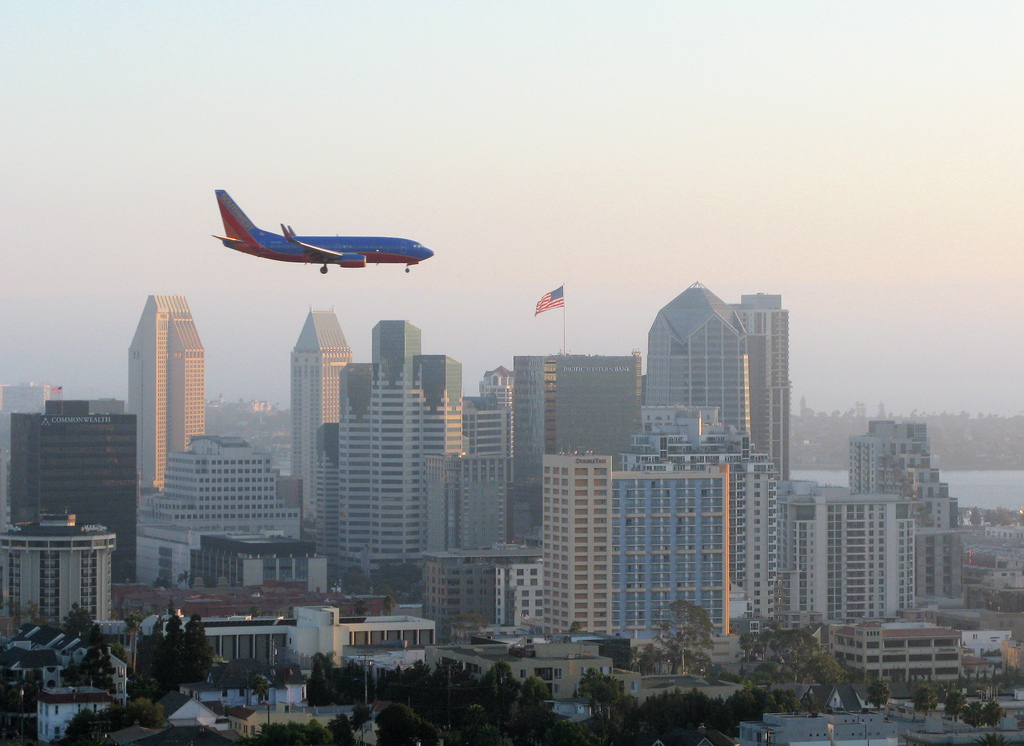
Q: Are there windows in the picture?
A: Yes, there are windows.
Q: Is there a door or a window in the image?
A: Yes, there are windows.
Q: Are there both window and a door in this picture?
A: No, there are windows but no doors.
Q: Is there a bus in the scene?
A: No, there are no buses.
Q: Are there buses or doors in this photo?
A: No, there are no buses or doors.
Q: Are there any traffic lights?
A: No, there are no traffic lights.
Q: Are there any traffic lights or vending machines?
A: No, there are no traffic lights or vending machines.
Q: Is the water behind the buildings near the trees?
A: Yes, the water is behind the buildings.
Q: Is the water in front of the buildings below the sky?
A: No, the water is behind the buildings.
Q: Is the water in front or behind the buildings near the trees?
A: The water is behind the buildings.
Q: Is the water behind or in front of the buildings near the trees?
A: The water is behind the buildings.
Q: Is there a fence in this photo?
A: No, there are no fences.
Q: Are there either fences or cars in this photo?
A: No, there are no fences or cars.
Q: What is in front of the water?
A: The buildings are in front of the water.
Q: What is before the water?
A: The buildings are in front of the water.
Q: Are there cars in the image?
A: No, there are no cars.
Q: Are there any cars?
A: No, there are no cars.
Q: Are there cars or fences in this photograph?
A: No, there are no cars or fences.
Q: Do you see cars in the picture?
A: No, there are no cars.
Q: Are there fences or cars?
A: No, there are no cars or fences.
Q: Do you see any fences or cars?
A: No, there are no cars or fences.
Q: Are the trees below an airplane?
A: Yes, the trees are below an airplane.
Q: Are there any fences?
A: No, there are no fences.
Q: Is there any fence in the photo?
A: No, there are no fences.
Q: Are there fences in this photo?
A: No, there are no fences.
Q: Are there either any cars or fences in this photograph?
A: No, there are no fences or cars.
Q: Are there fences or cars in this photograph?
A: No, there are no fences or cars.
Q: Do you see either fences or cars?
A: No, there are no fences or cars.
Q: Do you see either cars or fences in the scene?
A: No, there are no fences or cars.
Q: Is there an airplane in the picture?
A: Yes, there is an airplane.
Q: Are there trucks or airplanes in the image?
A: Yes, there is an airplane.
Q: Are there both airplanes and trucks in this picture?
A: No, there is an airplane but no trucks.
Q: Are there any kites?
A: No, there are no kites.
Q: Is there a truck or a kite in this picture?
A: No, there are no kites or trucks.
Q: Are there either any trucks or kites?
A: No, there are no kites or trucks.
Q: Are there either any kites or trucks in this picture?
A: No, there are no kites or trucks.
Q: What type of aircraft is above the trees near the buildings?
A: The aircraft is an airplane.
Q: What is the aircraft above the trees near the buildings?
A: The aircraft is an airplane.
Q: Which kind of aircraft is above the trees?
A: The aircraft is an airplane.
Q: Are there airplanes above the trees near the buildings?
A: Yes, there is an airplane above the trees.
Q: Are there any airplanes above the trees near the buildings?
A: Yes, there is an airplane above the trees.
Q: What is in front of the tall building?
A: The airplane is in front of the building.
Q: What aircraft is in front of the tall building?
A: The aircraft is an airplane.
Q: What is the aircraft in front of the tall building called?
A: The aircraft is an airplane.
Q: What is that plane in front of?
A: The plane is in front of the building.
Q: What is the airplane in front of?
A: The plane is in front of the building.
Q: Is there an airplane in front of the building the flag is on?
A: Yes, there is an airplane in front of the building.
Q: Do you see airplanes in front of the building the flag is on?
A: Yes, there is an airplane in front of the building.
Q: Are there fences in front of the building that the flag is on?
A: No, there is an airplane in front of the building.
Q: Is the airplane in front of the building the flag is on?
A: Yes, the airplane is in front of the building.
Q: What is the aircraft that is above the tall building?
A: The aircraft is an airplane.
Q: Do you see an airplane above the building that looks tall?
A: Yes, there is an airplane above the building.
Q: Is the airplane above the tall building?
A: Yes, the airplane is above the building.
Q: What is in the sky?
A: The airplane is in the sky.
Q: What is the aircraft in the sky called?
A: The aircraft is an airplane.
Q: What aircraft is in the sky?
A: The aircraft is an airplane.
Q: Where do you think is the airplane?
A: The airplane is in the sky.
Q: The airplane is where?
A: The airplane is in the sky.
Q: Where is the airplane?
A: The airplane is in the sky.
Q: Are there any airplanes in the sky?
A: Yes, there is an airplane in the sky.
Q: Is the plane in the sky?
A: Yes, the plane is in the sky.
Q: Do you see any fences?
A: No, there are no fences.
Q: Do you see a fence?
A: No, there are no fences.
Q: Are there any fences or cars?
A: No, there are no fences or cars.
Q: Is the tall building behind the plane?
A: Yes, the building is behind the plane.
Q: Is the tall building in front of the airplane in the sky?
A: No, the building is behind the airplane.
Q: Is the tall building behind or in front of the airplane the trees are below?
A: The building is behind the plane.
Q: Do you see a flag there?
A: Yes, there is a flag.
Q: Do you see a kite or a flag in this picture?
A: Yes, there is a flag.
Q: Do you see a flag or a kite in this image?
A: Yes, there is a flag.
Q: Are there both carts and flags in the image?
A: No, there is a flag but no carts.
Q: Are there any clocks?
A: No, there are no clocks.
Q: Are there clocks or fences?
A: No, there are no clocks or fences.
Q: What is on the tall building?
A: The flag is on the building.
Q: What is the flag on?
A: The flag is on the building.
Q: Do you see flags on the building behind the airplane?
A: Yes, there is a flag on the building.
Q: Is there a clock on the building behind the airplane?
A: No, there is a flag on the building.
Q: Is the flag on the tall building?
A: Yes, the flag is on the building.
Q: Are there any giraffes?
A: No, there are no giraffes.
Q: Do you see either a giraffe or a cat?
A: No, there are no giraffes or cats.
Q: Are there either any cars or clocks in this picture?
A: No, there are no cars or clocks.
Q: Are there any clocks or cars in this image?
A: No, there are no cars or clocks.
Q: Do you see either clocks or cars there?
A: No, there are no cars or clocks.